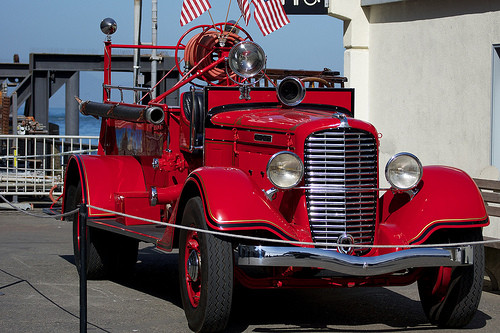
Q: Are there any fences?
A: Yes, there is a fence.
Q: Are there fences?
A: Yes, there is a fence.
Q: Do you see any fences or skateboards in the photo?
A: Yes, there is a fence.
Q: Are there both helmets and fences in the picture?
A: No, there is a fence but no helmets.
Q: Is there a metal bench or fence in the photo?
A: Yes, there is a metal fence.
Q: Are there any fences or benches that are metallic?
A: Yes, the fence is metallic.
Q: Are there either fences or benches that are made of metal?
A: Yes, the fence is made of metal.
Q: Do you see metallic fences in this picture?
A: Yes, there is a metal fence.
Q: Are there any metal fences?
A: Yes, there is a metal fence.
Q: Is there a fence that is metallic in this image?
A: Yes, there is a metal fence.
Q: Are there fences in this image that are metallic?
A: Yes, there is a fence that is metallic.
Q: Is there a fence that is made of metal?
A: Yes, there is a fence that is made of metal.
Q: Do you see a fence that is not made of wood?
A: Yes, there is a fence that is made of metal.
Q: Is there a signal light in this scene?
A: No, there are no traffic lights.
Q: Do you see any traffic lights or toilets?
A: No, there are no traffic lights or toilets.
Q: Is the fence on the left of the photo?
A: Yes, the fence is on the left of the image.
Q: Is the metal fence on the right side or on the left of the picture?
A: The fence is on the left of the image.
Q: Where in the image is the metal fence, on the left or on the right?
A: The fence is on the left of the image.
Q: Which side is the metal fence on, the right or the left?
A: The fence is on the left of the image.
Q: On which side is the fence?
A: The fence is on the left of the image.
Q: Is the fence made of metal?
A: Yes, the fence is made of metal.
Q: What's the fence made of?
A: The fence is made of metal.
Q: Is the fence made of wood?
A: No, the fence is made of metal.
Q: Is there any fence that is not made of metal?
A: No, there is a fence but it is made of metal.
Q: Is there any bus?
A: No, there are no buses.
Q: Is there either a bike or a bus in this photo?
A: No, there are no buses or bikes.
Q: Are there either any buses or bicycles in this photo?
A: No, there are no buses or bicycles.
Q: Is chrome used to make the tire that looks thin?
A: No, the tire is made of rubber.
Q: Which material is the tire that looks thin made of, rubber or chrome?
A: The tire is made of rubber.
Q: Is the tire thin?
A: Yes, the tire is thin.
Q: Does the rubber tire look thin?
A: Yes, the tire is thin.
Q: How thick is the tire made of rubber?
A: The tire is thin.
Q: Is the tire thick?
A: No, the tire is thin.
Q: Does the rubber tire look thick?
A: No, the tire is thin.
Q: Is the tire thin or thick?
A: The tire is thin.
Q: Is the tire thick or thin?
A: The tire is thin.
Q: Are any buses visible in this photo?
A: No, there are no buses.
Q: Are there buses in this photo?
A: No, there are no buses.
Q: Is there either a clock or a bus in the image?
A: No, there are no buses or clocks.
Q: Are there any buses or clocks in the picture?
A: No, there are no buses or clocks.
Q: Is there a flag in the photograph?
A: Yes, there is a flag.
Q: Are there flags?
A: Yes, there is a flag.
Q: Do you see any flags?
A: Yes, there is a flag.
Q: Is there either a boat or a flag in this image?
A: Yes, there is a flag.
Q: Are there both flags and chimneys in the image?
A: No, there is a flag but no chimneys.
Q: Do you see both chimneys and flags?
A: No, there is a flag but no chimneys.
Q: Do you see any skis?
A: No, there are no skis.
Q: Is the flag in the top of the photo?
A: Yes, the flag is in the top of the image.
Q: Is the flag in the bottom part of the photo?
A: No, the flag is in the top of the image.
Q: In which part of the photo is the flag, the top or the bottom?
A: The flag is in the top of the image.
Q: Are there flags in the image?
A: Yes, there is a flag.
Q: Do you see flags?
A: Yes, there is a flag.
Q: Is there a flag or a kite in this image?
A: Yes, there is a flag.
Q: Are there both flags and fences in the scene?
A: Yes, there are both a flag and a fence.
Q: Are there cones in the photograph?
A: No, there are no cones.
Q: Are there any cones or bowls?
A: No, there are no cones or bowls.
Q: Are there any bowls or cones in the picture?
A: No, there are no cones or bowls.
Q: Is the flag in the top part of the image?
A: Yes, the flag is in the top of the image.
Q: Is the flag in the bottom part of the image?
A: No, the flag is in the top of the image.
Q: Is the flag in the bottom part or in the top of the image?
A: The flag is in the top of the image.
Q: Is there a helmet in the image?
A: No, there are no helmets.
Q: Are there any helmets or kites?
A: No, there are no helmets or kites.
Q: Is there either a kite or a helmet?
A: No, there are no helmets or kites.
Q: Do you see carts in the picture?
A: No, there are no carts.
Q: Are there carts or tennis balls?
A: No, there are no carts or tennis balls.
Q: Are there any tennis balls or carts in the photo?
A: No, there are no carts or tennis balls.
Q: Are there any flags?
A: Yes, there is a flag.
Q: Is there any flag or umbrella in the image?
A: Yes, there is a flag.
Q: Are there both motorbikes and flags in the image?
A: No, there is a flag but no motorcycles.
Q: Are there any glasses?
A: No, there are no glasses.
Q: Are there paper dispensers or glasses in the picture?
A: No, there are no glasses or paper dispensers.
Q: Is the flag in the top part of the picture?
A: Yes, the flag is in the top of the image.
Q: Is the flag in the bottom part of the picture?
A: No, the flag is in the top of the image.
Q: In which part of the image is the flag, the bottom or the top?
A: The flag is in the top of the image.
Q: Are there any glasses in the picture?
A: No, there are no glasses.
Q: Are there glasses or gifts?
A: No, there are no glasses or gifts.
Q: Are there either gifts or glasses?
A: No, there are no glasses or gifts.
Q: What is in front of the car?
A: The grill is in front of the car.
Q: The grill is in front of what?
A: The grill is in front of the car.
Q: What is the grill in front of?
A: The grill is in front of the car.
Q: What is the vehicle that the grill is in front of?
A: The vehicle is a car.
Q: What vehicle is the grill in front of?
A: The grill is in front of the car.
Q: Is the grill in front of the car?
A: Yes, the grill is in front of the car.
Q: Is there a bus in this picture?
A: No, there are no buses.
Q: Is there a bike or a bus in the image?
A: No, there are no buses or bikes.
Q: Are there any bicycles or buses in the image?
A: No, there are no buses or bicycles.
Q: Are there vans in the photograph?
A: No, there are no vans.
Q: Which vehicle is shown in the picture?
A: The vehicle is a car.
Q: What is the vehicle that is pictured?
A: The vehicle is a car.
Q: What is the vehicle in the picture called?
A: The vehicle is a car.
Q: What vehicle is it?
A: The vehicle is a car.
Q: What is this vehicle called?
A: This is a car.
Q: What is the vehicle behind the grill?
A: The vehicle is a car.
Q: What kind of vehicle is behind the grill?
A: The vehicle is a car.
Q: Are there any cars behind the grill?
A: Yes, there is a car behind the grill.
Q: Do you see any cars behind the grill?
A: Yes, there is a car behind the grill.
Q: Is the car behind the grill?
A: Yes, the car is behind the grill.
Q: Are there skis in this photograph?
A: No, there are no skis.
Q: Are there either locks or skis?
A: No, there are no skis or locks.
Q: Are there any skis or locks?
A: No, there are no skis or locks.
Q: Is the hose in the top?
A: Yes, the hose is in the top of the image.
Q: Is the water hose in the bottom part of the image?
A: No, the water hose is in the top of the image.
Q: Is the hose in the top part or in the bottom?
A: The hose is in the top of the image.